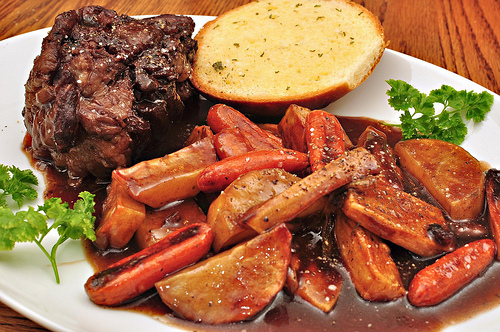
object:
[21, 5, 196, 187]
meat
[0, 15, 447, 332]
plate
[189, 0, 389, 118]
bun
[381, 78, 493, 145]
leaves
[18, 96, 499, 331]
sauce